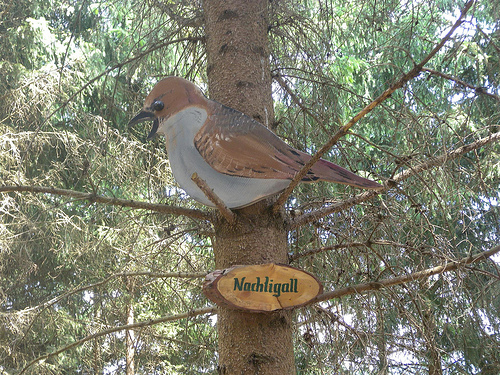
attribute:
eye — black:
[141, 94, 188, 124]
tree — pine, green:
[330, 81, 458, 140]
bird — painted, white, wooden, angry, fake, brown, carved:
[127, 71, 384, 220]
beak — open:
[123, 107, 157, 143]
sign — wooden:
[203, 261, 320, 313]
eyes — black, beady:
[146, 94, 172, 119]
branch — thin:
[272, 1, 472, 211]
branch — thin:
[293, 128, 498, 228]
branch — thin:
[289, 238, 499, 281]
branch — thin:
[319, 246, 499, 299]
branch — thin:
[4, 180, 213, 218]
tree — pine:
[1, 2, 498, 372]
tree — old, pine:
[24, 9, 488, 357]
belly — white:
[162, 151, 280, 208]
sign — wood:
[207, 257, 323, 317]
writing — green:
[234, 270, 298, 295]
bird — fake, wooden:
[129, 78, 391, 208]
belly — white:
[177, 158, 281, 208]